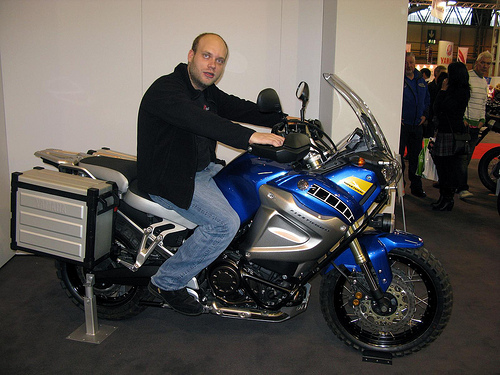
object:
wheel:
[317, 243, 458, 360]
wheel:
[52, 250, 158, 322]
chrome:
[360, 286, 408, 325]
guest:
[429, 61, 473, 212]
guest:
[459, 48, 491, 203]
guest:
[400, 51, 432, 198]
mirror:
[295, 80, 310, 123]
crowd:
[429, 61, 474, 213]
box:
[8, 165, 121, 273]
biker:
[133, 31, 310, 317]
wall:
[0, 0, 401, 181]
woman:
[429, 61, 473, 212]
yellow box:
[343, 175, 375, 196]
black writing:
[289, 209, 331, 233]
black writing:
[343, 181, 363, 194]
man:
[135, 31, 309, 317]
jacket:
[135, 61, 291, 211]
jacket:
[399, 68, 433, 128]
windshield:
[321, 72, 393, 159]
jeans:
[146, 161, 242, 292]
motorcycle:
[32, 71, 455, 360]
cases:
[7, 163, 116, 268]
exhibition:
[0, 0, 500, 375]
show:
[0, 0, 500, 375]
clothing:
[430, 85, 472, 134]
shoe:
[146, 280, 206, 317]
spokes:
[349, 318, 362, 323]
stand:
[64, 272, 119, 345]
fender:
[322, 229, 425, 276]